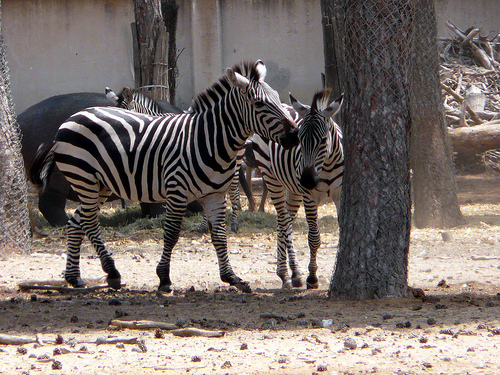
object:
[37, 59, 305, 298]
zebra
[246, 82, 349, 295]
zebra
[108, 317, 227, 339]
sticks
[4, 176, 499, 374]
ground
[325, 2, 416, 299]
tree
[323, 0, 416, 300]
pattern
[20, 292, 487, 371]
rocks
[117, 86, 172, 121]
zebra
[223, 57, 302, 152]
head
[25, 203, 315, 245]
grass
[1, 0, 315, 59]
wall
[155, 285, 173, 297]
hoof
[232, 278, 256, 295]
hoof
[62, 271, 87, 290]
hoof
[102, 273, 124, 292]
hoof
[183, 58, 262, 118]
mane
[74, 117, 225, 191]
stripes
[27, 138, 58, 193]
tail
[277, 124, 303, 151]
nose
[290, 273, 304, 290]
hooves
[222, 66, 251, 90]
ears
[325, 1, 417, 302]
bark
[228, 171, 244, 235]
leg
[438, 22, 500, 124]
wood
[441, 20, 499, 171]
pile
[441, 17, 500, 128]
sticks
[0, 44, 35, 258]
fence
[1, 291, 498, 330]
shadow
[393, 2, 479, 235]
trees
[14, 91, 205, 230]
animal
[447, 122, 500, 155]
log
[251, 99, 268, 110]
eye